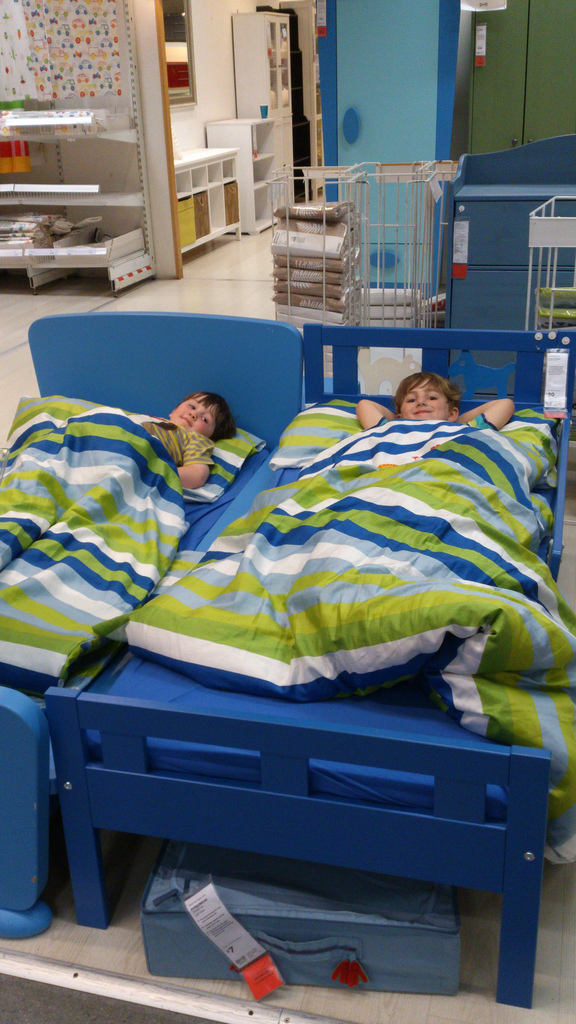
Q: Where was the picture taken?
A: In a nursery of a business.